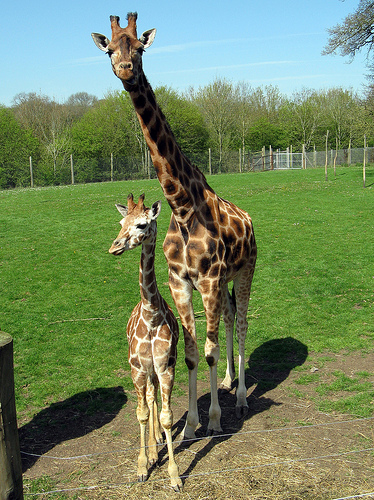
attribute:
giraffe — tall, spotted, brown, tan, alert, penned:
[92, 11, 258, 441]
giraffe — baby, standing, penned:
[110, 193, 183, 496]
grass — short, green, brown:
[2, 166, 372, 498]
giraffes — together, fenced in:
[90, 8, 258, 494]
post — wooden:
[28, 156, 36, 190]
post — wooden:
[69, 151, 77, 185]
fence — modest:
[2, 140, 373, 190]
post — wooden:
[108, 149, 114, 184]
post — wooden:
[145, 149, 152, 183]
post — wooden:
[207, 145, 214, 179]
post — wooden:
[237, 147, 244, 179]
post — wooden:
[285, 145, 291, 170]